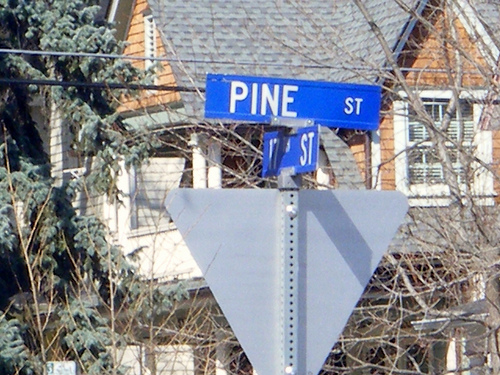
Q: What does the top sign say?
A: Pine street.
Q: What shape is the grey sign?
A: Triangle.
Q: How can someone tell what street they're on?
A: Street signs.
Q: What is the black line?
A: Power line.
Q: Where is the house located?
A: Corner of 17th and Pine.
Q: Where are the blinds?
A: In the windows.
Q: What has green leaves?
A: Tree.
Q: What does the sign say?
A: Pine st.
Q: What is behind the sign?
A: A house.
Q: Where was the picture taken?
A: At street corner.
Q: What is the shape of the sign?
A: Rectangle.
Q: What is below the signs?
A: A yield sign.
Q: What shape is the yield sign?
A: Triangle.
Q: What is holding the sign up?
A: A metal rod.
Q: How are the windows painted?
A: White.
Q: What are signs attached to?
A: Grey pole.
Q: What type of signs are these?
A: Street signs.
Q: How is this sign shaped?
A: Triangle.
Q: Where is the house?
A: Behind signs.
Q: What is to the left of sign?
A: Large tree.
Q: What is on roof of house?
A: Shingles.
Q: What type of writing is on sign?
A: White.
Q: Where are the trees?
A: Next to house.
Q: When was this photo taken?
A: During the daytime.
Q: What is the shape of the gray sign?
A: Triangle.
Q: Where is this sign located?
A: At an intersection.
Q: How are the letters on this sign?
A: All capitals.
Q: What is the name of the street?
A: Pine Street.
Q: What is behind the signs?
A: A house.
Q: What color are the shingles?
A: Gray.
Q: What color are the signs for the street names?
A: Blue.